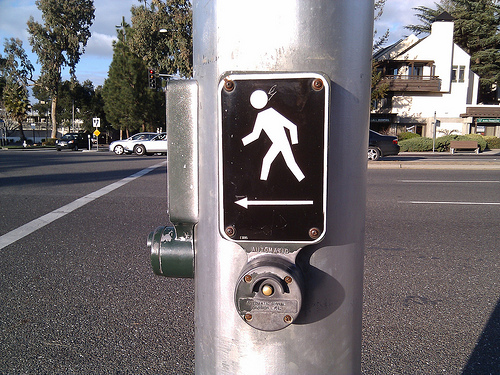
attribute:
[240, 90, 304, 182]
figure — human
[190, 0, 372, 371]
pole — shiny metal, thick, metallic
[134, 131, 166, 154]
motor vehicle — white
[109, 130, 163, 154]
motor vehicle — white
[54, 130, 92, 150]
car — black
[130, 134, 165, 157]
car — white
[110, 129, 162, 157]
car — white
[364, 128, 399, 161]
car — black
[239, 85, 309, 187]
person — white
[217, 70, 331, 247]
sign — cross walk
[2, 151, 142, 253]
paint — white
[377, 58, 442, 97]
porch — wood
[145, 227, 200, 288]
light switch — green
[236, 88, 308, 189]
symbol — man walking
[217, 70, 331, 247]
crosswalk sign — black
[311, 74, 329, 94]
screw — rusty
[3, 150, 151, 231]
line — white painted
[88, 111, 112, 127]
road sign — black, white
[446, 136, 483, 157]
bench — brown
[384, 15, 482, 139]
house — white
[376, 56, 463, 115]
balcony — wood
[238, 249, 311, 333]
button — to activate crosswalk sign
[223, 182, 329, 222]
arrow — pointing to left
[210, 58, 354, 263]
sign — black, white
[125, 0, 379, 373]
pole — metal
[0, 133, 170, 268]
line — thick, white